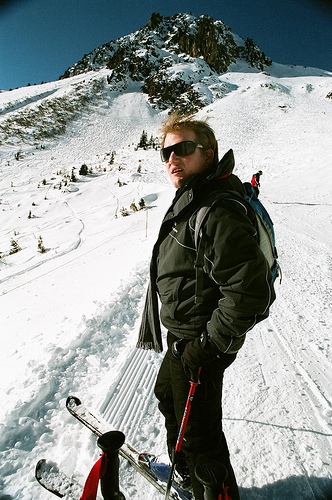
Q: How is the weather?
A: It is clear.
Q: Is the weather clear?
A: Yes, it is clear.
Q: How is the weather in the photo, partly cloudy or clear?
A: It is clear.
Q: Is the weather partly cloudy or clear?
A: It is clear.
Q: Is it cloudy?
A: No, it is clear.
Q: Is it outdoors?
A: Yes, it is outdoors.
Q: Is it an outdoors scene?
A: Yes, it is outdoors.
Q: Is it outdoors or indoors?
A: It is outdoors.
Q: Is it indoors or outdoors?
A: It is outdoors.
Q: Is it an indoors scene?
A: No, it is outdoors.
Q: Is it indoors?
A: No, it is outdoors.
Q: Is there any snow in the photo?
A: Yes, there is snow.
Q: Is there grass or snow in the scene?
A: Yes, there is snow.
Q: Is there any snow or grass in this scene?
A: Yes, there is snow.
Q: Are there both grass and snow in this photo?
A: No, there is snow but no grass.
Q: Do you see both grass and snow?
A: No, there is snow but no grass.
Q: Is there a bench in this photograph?
A: No, there are no benches.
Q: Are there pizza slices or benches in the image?
A: No, there are no benches or pizza slices.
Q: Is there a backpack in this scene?
A: Yes, there is a backpack.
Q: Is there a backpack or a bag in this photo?
A: Yes, there is a backpack.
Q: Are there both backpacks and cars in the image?
A: No, there is a backpack but no cars.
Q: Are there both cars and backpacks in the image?
A: No, there is a backpack but no cars.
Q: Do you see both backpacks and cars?
A: No, there is a backpack but no cars.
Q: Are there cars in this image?
A: No, there are no cars.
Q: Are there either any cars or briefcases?
A: No, there are no cars or briefcases.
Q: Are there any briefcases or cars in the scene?
A: No, there are no cars or briefcases.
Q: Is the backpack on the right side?
A: Yes, the backpack is on the right of the image.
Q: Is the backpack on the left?
A: No, the backpack is on the right of the image.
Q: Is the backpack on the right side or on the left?
A: The backpack is on the right of the image.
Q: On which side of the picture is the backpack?
A: The backpack is on the right of the image.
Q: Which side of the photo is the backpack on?
A: The backpack is on the right of the image.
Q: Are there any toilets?
A: No, there are no toilets.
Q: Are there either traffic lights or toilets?
A: No, there are no toilets or traffic lights.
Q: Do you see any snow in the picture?
A: Yes, there is snow.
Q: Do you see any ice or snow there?
A: Yes, there is snow.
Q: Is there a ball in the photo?
A: No, there are no balls.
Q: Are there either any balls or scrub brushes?
A: No, there are no balls or scrub brushes.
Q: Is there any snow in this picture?
A: Yes, there is snow.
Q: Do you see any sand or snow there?
A: Yes, there is snow.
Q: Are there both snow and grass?
A: No, there is snow but no grass.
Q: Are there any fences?
A: No, there are no fences.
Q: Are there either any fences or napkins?
A: No, there are no fences or napkins.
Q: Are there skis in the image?
A: Yes, there are skis.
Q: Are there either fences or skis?
A: Yes, there are skis.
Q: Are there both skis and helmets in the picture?
A: No, there are skis but no helmets.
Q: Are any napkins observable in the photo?
A: No, there are no napkins.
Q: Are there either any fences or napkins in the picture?
A: No, there are no napkins or fences.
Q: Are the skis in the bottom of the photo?
A: Yes, the skis are in the bottom of the image.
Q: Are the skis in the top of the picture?
A: No, the skis are in the bottom of the image.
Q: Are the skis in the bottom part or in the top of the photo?
A: The skis are in the bottom of the image.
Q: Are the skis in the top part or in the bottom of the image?
A: The skis are in the bottom of the image.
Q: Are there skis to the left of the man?
A: Yes, there are skis to the left of the man.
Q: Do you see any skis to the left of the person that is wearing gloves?
A: Yes, there are skis to the left of the man.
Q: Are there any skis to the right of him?
A: No, the skis are to the left of the man.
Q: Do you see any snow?
A: Yes, there is snow.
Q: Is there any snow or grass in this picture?
A: Yes, there is snow.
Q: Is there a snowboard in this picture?
A: No, there are no snowboards.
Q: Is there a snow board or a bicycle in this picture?
A: No, there are no snowboards or bicycles.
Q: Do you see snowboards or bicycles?
A: No, there are no snowboards or bicycles.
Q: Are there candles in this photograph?
A: No, there are no candles.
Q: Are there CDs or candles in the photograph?
A: No, there are no candles or cds.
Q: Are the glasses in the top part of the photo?
A: Yes, the glasses are in the top of the image.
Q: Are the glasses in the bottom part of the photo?
A: No, the glasses are in the top of the image.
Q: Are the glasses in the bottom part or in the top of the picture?
A: The glasses are in the top of the image.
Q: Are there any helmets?
A: No, there are no helmets.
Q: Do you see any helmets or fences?
A: No, there are no helmets or fences.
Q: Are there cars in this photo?
A: No, there are no cars.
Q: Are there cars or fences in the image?
A: No, there are no cars or fences.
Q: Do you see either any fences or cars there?
A: No, there are no cars or fences.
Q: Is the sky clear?
A: Yes, the sky is clear.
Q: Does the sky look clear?
A: Yes, the sky is clear.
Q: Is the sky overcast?
A: No, the sky is clear.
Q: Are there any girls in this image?
A: No, there are no girls.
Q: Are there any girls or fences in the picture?
A: No, there are no girls or fences.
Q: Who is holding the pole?
A: The man is holding the pole.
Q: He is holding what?
A: The man is holding the pole.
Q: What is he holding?
A: The man is holding the pole.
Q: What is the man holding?
A: The man is holding the pole.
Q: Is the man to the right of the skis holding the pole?
A: Yes, the man is holding the pole.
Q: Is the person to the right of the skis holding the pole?
A: Yes, the man is holding the pole.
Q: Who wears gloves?
A: The man wears gloves.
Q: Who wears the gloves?
A: The man wears gloves.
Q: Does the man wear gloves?
A: Yes, the man wears gloves.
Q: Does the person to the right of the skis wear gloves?
A: Yes, the man wears gloves.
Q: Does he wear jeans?
A: No, the man wears gloves.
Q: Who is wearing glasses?
A: The man is wearing glasses.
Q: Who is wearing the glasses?
A: The man is wearing glasses.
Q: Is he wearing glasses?
A: Yes, the man is wearing glasses.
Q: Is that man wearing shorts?
A: No, the man is wearing glasses.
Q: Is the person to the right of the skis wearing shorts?
A: No, the man is wearing glasses.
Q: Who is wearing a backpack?
A: The man is wearing a backpack.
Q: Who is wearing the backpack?
A: The man is wearing a backpack.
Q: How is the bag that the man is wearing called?
A: The bag is a backpack.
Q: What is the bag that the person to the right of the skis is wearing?
A: The bag is a backpack.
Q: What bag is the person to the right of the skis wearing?
A: The man is wearing a backpack.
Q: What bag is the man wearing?
A: The man is wearing a backpack.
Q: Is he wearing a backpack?
A: Yes, the man is wearing a backpack.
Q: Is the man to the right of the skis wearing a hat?
A: No, the man is wearing a backpack.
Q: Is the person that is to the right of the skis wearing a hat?
A: No, the man is wearing a backpack.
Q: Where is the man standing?
A: The man is standing in the skis.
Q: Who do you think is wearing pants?
A: The man is wearing pants.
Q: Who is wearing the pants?
A: The man is wearing pants.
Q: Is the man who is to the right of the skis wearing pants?
A: Yes, the man is wearing pants.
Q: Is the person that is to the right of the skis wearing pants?
A: Yes, the man is wearing pants.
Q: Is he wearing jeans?
A: No, the man is wearing pants.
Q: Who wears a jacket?
A: The man wears a jacket.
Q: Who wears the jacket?
A: The man wears a jacket.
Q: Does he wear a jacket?
A: Yes, the man wears a jacket.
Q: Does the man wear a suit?
A: No, the man wears a jacket.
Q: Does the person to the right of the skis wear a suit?
A: No, the man wears a jacket.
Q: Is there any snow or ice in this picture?
A: Yes, there is snow.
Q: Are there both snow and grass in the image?
A: No, there is snow but no grass.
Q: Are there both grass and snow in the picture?
A: No, there is snow but no grass.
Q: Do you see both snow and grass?
A: No, there is snow but no grass.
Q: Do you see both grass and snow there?
A: No, there is snow but no grass.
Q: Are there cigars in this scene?
A: No, there are no cigars.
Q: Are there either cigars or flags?
A: No, there are no cigars or flags.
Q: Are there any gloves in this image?
A: Yes, there are gloves.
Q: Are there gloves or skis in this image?
A: Yes, there are gloves.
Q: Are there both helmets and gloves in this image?
A: No, there are gloves but no helmets.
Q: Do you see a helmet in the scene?
A: No, there are no helmets.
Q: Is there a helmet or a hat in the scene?
A: No, there are no helmets or hats.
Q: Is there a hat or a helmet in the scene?
A: No, there are no helmets or hats.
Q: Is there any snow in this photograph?
A: Yes, there is snow.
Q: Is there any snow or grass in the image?
A: Yes, there is snow.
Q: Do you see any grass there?
A: No, there is no grass.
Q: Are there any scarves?
A: Yes, there is a scarf.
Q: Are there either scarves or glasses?
A: Yes, there is a scarf.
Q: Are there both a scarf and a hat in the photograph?
A: No, there is a scarf but no hats.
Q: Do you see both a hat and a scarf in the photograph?
A: No, there is a scarf but no hats.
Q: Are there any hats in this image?
A: No, there are no hats.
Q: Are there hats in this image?
A: No, there are no hats.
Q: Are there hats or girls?
A: No, there are no hats or girls.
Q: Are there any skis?
A: Yes, there are skis.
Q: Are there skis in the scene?
A: Yes, there are skis.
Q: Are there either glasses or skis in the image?
A: Yes, there are skis.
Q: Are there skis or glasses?
A: Yes, there are skis.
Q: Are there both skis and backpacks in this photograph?
A: Yes, there are both skis and a backpack.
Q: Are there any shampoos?
A: No, there are no shampoos.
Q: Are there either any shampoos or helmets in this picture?
A: No, there are no shampoos or helmets.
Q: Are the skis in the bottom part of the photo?
A: Yes, the skis are in the bottom of the image.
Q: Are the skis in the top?
A: No, the skis are in the bottom of the image.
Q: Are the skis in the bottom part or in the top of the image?
A: The skis are in the bottom of the image.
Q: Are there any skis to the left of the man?
A: Yes, there are skis to the left of the man.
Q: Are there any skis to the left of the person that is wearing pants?
A: Yes, there are skis to the left of the man.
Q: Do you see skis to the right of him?
A: No, the skis are to the left of the man.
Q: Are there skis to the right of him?
A: No, the skis are to the left of the man.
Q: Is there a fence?
A: No, there are no fences.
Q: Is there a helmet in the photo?
A: No, there are no helmets.